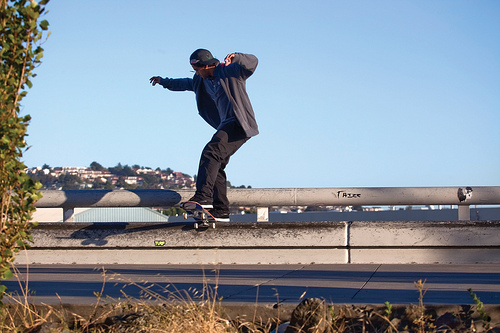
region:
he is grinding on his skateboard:
[120, 10, 326, 283]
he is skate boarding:
[130, 16, 294, 252]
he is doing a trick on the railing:
[117, 14, 280, 231]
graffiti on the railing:
[325, 185, 400, 221]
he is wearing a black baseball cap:
[122, 27, 306, 243]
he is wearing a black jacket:
[132, 26, 319, 156]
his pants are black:
[174, 103, 260, 210]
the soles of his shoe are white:
[185, 195, 246, 229]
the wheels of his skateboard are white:
[172, 210, 224, 232]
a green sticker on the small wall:
[143, 231, 170, 246]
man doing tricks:
[148, 44, 283, 247]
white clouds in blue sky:
[358, 40, 401, 74]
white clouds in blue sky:
[343, 10, 435, 91]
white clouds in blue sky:
[54, 38, 107, 65]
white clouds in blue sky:
[75, 96, 124, 136]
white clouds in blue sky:
[307, 113, 339, 147]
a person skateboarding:
[136, 40, 274, 251]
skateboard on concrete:
[160, 185, 241, 242]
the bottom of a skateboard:
[162, 194, 221, 241]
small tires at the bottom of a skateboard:
[166, 192, 220, 242]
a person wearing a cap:
[160, 34, 235, 89]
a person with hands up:
[145, 41, 275, 94]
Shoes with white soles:
[182, 190, 238, 226]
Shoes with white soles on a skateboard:
[165, 186, 236, 227]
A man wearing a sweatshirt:
[140, 42, 269, 140]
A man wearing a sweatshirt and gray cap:
[132, 42, 270, 142]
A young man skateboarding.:
[130, 25, 268, 235]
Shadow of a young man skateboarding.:
[58, 170, 191, 254]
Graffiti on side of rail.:
[331, 188, 374, 205]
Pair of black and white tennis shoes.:
[182, 187, 229, 222]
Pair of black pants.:
[190, 117, 240, 202]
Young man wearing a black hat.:
[178, 41, 231, 94]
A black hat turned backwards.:
[183, 46, 224, 75]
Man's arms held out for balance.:
[137, 40, 272, 148]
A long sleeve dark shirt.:
[141, 48, 270, 138]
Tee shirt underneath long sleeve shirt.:
[145, 42, 270, 141]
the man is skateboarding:
[104, 15, 301, 245]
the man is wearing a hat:
[168, 26, 238, 93]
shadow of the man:
[34, 153, 186, 250]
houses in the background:
[27, 142, 186, 189]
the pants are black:
[177, 109, 274, 217]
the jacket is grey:
[147, 38, 281, 141]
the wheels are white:
[171, 208, 208, 223]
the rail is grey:
[246, 157, 479, 220]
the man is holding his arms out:
[132, 27, 296, 112]